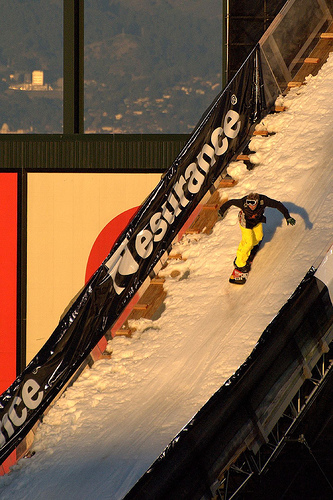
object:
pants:
[234, 223, 265, 268]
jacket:
[218, 192, 291, 231]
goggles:
[245, 199, 257, 207]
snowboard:
[229, 254, 254, 288]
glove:
[287, 215, 295, 224]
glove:
[217, 210, 224, 221]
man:
[218, 192, 297, 274]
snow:
[0, 51, 333, 498]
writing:
[135, 108, 242, 260]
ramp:
[0, 25, 333, 498]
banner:
[0, 42, 271, 466]